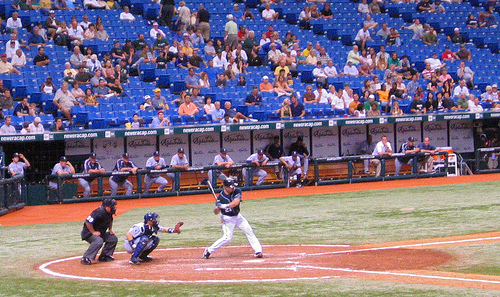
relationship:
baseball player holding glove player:
[119, 209, 186, 271] [202, 177, 265, 259]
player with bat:
[202, 177, 265, 259] [203, 179, 220, 204]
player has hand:
[202, 177, 265, 259] [216, 201, 231, 212]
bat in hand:
[203, 179, 220, 204] [216, 201, 231, 212]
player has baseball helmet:
[202, 177, 265, 259] [221, 174, 240, 191]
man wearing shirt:
[440, 41, 461, 63] [440, 49, 455, 62]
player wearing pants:
[202, 177, 265, 259] [209, 211, 261, 255]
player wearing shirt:
[207, 174, 264, 259] [213, 187, 243, 216]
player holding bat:
[202, 177, 265, 259] [204, 176, 222, 210]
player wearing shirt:
[202, 177, 265, 259] [215, 185, 245, 217]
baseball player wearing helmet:
[122, 210, 185, 265] [142, 210, 162, 231]